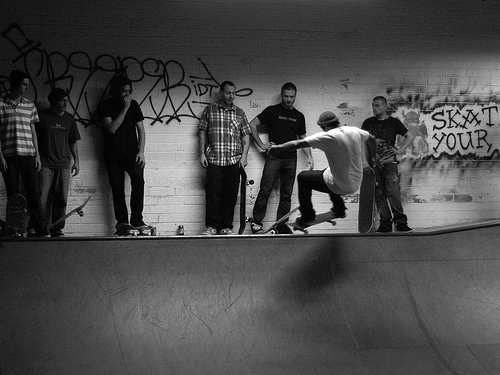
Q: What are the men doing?
A: Standing by the ramp.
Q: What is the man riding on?
A: A skateboard.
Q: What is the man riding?
A: A ramp.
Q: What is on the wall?
A: Graffiti.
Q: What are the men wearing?
A: Shirts and pants.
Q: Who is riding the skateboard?
A: A man.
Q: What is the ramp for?
A: To ride on.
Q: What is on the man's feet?
A: Sneakers.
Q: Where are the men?
A: At the skate park?.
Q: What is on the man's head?
A: A hat.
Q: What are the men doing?
A: Skateboarding.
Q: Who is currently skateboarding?
A: Man in white shirt.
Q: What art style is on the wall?
A: Graffiti.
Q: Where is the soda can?
A: By man in plaid.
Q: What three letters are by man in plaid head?
A: Idt.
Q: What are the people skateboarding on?
A: Skate ramp.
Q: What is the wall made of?
A: Bricks.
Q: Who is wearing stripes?
A: Man at left end.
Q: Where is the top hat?
A: On wall.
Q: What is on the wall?
A: Graffiti.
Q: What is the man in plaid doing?
A: Holding a skateboard.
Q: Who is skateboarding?
A: The man in white shirt.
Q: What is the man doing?
A: Skateboarding.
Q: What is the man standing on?
A: Skateboard.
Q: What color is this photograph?
A: Black and white.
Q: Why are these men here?
A: To skateboard.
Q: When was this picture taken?
A: Evening.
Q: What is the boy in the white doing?
A: Jumping.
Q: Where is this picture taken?
A: A skate park.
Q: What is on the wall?
A: Graffiti.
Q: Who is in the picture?
A: Seven men.